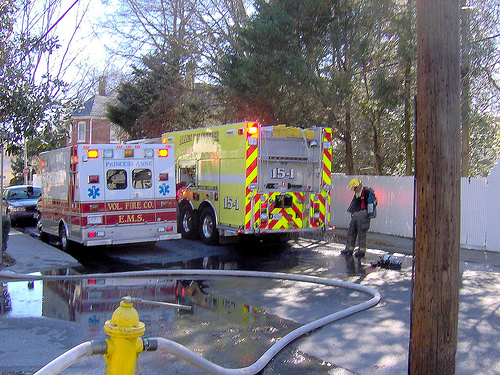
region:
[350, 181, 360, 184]
man wearing yellow helmet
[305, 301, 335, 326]
hose to the right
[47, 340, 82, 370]
hose to the left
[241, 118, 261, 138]
light on truck left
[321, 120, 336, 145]
light on truck right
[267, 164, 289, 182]
number fifteen on truck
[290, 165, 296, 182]
number one on truck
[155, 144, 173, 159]
light top right ambulance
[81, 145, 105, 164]
light on left ambulance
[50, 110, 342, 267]
ambulance and truck in street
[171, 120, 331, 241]
a yellow fire truck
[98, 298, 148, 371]
a yellow fire hydrant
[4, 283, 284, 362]
large puddle of water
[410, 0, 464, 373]
tall wooden post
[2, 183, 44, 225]
a black car parked on the road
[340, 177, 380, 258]
a fire fighter standing on the road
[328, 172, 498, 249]
the fence is painted white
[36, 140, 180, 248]
an ambulance is parked on the street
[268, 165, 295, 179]
the fire engine number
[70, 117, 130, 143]
a red brick house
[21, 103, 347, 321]
a fire truck and ambulance parked in the street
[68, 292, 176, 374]
a yellow fire hydrant with two fire hoses attached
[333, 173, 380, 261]
a fireman looking down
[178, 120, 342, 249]
a yellow and red fire truck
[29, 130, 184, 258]
a white and red ambulance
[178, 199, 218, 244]
the rear wheels of a fire truck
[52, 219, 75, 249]
the rear wheel of an ambulance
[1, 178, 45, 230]
a car parked in front of the ambulance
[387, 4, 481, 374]
a wooden telephone pole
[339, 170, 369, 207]
a fireman with a yellow helmet on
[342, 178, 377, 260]
Firefighter waiting without full gear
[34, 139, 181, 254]
Parked ambulence waiting for patient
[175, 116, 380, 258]
Firefighter waiting by fire truck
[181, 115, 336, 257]
Parked firetruck on the side of the road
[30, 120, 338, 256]
Parked firetruck and ambulence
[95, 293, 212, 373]
Fire hydrant with hose attached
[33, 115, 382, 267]
Ambulence and fire truck with waiting firefighter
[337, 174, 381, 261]
Firefighter waiting for something alone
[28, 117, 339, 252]
Ambulence and Firetruck parked next to each other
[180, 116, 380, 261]
Firefighter waiting behind parked fire truck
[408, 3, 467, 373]
a telephone pole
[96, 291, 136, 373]
a yellow fire hydrant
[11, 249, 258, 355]
water on the ground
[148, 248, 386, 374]
a white hose hooked to the fire hydrant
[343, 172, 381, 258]
a man with a yellow hat on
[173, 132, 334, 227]
a yellow fire truck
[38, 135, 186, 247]
an ambulance parked on the street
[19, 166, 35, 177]
a stop sign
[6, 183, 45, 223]
a car parked on the street